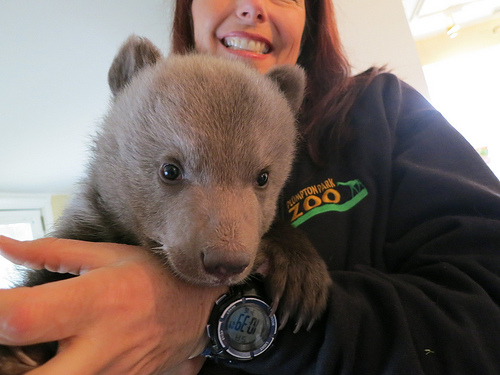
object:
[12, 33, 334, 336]
baby bear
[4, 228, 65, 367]
food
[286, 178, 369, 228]
logo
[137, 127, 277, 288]
pupy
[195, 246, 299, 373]
wrist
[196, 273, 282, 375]
watch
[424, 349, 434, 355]
lint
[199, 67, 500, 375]
sweatshirt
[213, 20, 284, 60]
smile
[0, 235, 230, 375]
hand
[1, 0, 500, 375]
lady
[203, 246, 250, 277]
nose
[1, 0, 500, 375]
woman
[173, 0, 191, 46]
hair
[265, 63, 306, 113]
ear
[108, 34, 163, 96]
ear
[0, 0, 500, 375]
person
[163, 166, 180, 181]
eye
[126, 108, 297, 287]
face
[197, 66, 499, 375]
sweater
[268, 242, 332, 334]
paw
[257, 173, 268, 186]
eye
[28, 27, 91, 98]
ceiling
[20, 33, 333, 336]
bear cub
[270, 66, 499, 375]
arm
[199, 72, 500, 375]
jacket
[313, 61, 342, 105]
hair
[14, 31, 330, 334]
puppy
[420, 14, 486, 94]
opening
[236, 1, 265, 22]
nose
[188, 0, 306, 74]
face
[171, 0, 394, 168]
head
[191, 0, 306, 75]
woman's face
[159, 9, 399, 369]
woman